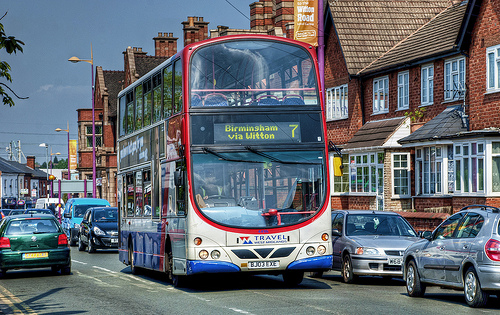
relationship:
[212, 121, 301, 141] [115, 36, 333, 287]
sign on bus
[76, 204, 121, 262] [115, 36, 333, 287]
car behind bus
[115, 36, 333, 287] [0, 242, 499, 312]
bus on street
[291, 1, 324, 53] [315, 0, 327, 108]
sign on pole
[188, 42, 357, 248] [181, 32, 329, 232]
bus front has border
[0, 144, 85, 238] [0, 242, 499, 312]
building down street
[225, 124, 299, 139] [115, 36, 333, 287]
sign on front of bus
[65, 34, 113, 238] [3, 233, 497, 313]
pole on side of street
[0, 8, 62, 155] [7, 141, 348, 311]
branches hanging over street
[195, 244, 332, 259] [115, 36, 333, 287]
headlights on front of bus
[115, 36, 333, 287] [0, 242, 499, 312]
bus in street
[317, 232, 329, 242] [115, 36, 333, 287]
left headlight on bus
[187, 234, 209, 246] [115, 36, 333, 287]
headlight on bus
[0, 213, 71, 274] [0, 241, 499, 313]
car on road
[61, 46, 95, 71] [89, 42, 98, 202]
streetlight on pole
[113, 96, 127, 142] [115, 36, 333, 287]
window on bus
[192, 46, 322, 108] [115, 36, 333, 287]
window on bus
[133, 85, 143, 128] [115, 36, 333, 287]
window on bus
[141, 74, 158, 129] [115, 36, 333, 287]
window on bus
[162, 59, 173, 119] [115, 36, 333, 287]
window on bus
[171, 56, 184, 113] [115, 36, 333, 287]
window on bus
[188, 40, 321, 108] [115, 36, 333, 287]
window on bus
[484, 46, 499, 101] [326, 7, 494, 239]
window on building